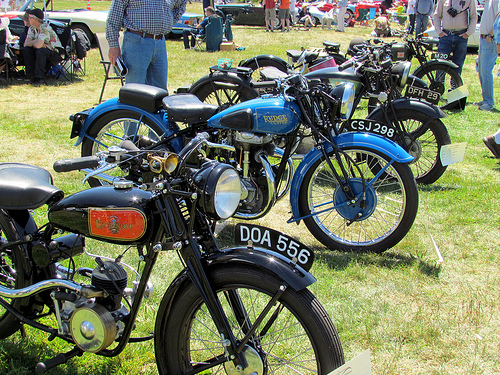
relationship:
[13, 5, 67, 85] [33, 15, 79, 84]
person sitting chair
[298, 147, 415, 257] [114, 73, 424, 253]
wheel of motorcycle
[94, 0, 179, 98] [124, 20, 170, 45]
person wearing belt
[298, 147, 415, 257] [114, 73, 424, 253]
wheel on a motorcycle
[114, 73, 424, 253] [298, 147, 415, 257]
motorcycle has wheel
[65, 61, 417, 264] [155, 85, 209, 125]
bike has seat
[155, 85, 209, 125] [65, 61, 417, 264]
seat on bike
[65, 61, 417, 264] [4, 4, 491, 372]
bike in grass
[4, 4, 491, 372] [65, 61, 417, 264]
grass has bike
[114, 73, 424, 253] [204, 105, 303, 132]
motorcycle has a motor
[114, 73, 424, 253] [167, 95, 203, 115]
motorcycle has a seat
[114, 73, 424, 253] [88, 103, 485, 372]
motorcycle on grass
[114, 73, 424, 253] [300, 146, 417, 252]
motorcycle with tire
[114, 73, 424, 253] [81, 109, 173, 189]
motorcycle with tire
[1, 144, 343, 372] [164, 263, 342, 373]
black motorcycle with tire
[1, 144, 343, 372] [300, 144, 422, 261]
black motorcycle with tire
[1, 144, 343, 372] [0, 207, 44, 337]
black motorcycle with tire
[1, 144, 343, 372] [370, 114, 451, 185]
black motorcycle with tire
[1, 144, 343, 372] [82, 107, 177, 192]
black motorcycle with tire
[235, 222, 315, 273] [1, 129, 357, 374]
license plate of a bike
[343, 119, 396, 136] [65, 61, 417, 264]
license plate of a bike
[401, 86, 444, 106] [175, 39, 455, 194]
license plate of a bike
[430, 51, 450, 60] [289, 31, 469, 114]
license plate of a bike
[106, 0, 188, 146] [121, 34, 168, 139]
man wearing jeans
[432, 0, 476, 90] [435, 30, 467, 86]
man wearing jeans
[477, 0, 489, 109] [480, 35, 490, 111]
man wearing jeans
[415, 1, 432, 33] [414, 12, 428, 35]
man wearing jeans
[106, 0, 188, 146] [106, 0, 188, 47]
man wearing shirt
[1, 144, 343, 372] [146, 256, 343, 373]
black motorcycle has wheel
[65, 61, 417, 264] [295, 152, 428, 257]
bike has wheel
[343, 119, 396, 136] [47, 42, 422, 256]
license plate on motorcycle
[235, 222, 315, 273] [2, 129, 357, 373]
license plate on motorcycle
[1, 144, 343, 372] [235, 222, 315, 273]
black motorcycle with license plate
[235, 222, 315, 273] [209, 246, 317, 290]
license plate on tire rim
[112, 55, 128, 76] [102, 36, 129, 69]
magazine in hand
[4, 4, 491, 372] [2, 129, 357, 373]
grass under motorcycle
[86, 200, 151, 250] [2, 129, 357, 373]
logo on motorcycle